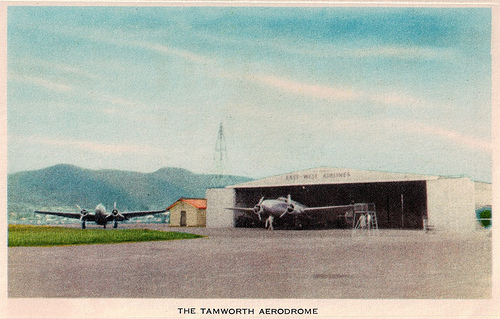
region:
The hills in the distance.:
[11, 165, 253, 228]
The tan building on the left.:
[158, 187, 201, 222]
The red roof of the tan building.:
[161, 191, 206, 209]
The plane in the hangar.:
[230, 193, 352, 226]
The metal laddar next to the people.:
[353, 203, 378, 237]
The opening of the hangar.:
[236, 188, 430, 228]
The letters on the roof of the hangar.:
[282, 169, 359, 184]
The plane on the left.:
[21, 195, 168, 230]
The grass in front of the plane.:
[1, 218, 201, 239]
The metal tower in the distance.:
[213, 111, 234, 187]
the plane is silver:
[213, 194, 392, 247]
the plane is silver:
[228, 183, 366, 233]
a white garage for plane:
[163, 160, 491, 253]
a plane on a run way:
[22, 198, 173, 226]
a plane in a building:
[225, 194, 372, 224]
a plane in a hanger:
[219, 190, 387, 227]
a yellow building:
[170, 198, 201, 225]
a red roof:
[163, 196, 208, 211]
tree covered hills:
[18, 163, 195, 209]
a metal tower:
[212, 120, 229, 183]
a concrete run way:
[30, 240, 470, 289]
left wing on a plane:
[311, 201, 370, 216]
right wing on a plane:
[225, 203, 253, 216]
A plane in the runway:
[28, 191, 202, 237]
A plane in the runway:
[35, 187, 157, 219]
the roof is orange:
[177, 189, 205, 209]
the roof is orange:
[139, 183, 216, 223]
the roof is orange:
[138, 182, 238, 252]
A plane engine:
[79, 210, 86, 215]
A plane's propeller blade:
[113, 201, 115, 208]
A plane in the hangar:
[258, 202, 295, 207]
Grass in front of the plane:
[41, 231, 136, 236]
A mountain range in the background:
[58, 183, 181, 195]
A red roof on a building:
[199, 200, 203, 205]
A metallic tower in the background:
[218, 148, 223, 175]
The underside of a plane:
[98, 214, 101, 221]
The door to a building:
[182, 216, 184, 223]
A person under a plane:
[268, 216, 274, 228]